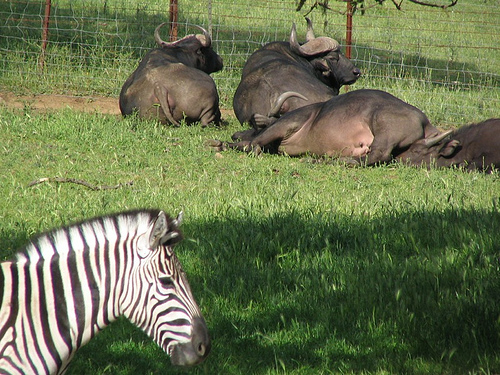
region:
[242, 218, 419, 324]
shadow in the grass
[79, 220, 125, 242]
hair on the zebra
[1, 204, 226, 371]
zebra is black and white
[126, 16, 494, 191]
animals laying down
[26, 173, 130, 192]
a stick in the grass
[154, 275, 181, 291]
the zebras eye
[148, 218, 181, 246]
the zebras ear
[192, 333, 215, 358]
the zebras nose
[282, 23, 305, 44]
horn on the animal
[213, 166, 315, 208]
the grass is tall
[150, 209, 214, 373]
This zebra has a lovely long face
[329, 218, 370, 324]
There is green grass here that is healthy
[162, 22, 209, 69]
There are sharp horns on these animals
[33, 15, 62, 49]
There is a brown post in the background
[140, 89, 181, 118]
There is a brown tail that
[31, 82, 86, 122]
There is a brown patch of dirt visible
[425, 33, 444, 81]
There is steel fence that is visible here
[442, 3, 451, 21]
There are some brown branches in the background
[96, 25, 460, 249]
Jackson Mingus took this photo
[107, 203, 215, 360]
The head of a zebra.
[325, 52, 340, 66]
The right eye of the horned animal.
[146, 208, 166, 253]
The right ear of a zebra.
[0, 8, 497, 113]
A section of fence.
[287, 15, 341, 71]
The horns of the animal with one eye visible.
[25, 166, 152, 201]
A stick laying in the grass.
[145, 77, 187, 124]
The tail of a horned animal.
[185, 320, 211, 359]
The nostril of a zebra.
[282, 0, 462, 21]
Tree branches hanging down into the cage.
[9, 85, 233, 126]
An area where th grass has been worn away.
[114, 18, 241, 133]
animal lying in a field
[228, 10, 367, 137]
animal lying in a field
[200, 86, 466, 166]
animal lying in a field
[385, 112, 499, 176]
animal lying in a field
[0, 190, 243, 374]
zebra in a field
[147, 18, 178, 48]
horn of a wildebeest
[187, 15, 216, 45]
horn of a wildebeest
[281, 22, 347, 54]
horn of a wildebeest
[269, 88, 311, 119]
horn of a wildebeest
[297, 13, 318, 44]
horn of a wildebeest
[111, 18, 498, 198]
several oxen laying in a field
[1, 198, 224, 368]
a zebra standing in the field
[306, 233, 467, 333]
green grass of the field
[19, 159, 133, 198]
a dead grey branch on the ground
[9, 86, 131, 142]
a patch of brown dirt in the field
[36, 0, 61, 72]
red metal post of the fence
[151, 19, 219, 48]
grey curled horns of the oxen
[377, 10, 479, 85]
grey chain link fence of the pen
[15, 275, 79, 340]
black and white stripes of the zebra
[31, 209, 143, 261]
black and white mane of the zebra